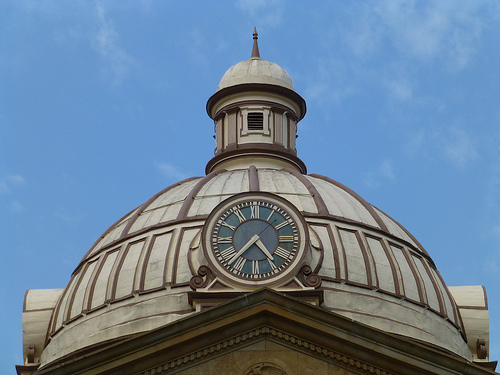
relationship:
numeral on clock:
[263, 206, 282, 221] [204, 198, 296, 277]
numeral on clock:
[277, 231, 299, 245] [202, 190, 307, 287]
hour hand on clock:
[253, 237, 273, 262] [210, 199, 300, 281]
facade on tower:
[441, 280, 484, 353] [15, 25, 496, 374]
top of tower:
[208, 27, 315, 124] [15, 26, 499, 375]